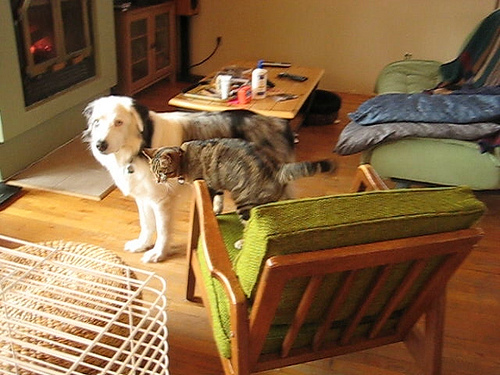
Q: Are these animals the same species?
A: No, they are dogs and cats.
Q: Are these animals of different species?
A: Yes, they are dogs and cats.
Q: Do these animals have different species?
A: Yes, they are dogs and cats.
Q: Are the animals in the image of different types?
A: Yes, they are dogs and cats.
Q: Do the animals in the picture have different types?
A: Yes, they are dogs and cats.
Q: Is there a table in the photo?
A: Yes, there is a table.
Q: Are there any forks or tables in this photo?
A: Yes, there is a table.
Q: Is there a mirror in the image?
A: No, there are no mirrors.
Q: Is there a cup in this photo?
A: Yes, there is a cup.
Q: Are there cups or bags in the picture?
A: Yes, there is a cup.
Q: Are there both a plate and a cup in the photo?
A: No, there is a cup but no plates.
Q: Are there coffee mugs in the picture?
A: No, there are no coffee mugs.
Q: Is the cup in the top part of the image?
A: Yes, the cup is in the top of the image.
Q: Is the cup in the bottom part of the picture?
A: No, the cup is in the top of the image.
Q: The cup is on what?
A: The cup is on the table.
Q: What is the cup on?
A: The cup is on the table.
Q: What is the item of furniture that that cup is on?
A: The piece of furniture is a table.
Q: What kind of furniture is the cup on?
A: The cup is on the table.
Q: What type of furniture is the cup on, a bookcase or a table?
A: The cup is on a table.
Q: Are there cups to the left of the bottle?
A: Yes, there is a cup to the left of the bottle.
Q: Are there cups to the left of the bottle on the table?
A: Yes, there is a cup to the left of the bottle.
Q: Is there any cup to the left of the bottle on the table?
A: Yes, there is a cup to the left of the bottle.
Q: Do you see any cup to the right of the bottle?
A: No, the cup is to the left of the bottle.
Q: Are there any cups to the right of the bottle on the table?
A: No, the cup is to the left of the bottle.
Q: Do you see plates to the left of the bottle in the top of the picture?
A: No, there is a cup to the left of the bottle.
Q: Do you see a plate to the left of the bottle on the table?
A: No, there is a cup to the left of the bottle.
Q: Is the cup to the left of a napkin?
A: No, the cup is to the left of the bottle.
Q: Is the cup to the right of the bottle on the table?
A: No, the cup is to the left of the bottle.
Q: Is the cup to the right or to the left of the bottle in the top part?
A: The cup is to the left of the bottle.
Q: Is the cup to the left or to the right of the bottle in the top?
A: The cup is to the left of the bottle.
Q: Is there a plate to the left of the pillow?
A: No, there is a cup to the left of the pillow.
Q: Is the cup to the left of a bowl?
A: No, the cup is to the left of the pillow.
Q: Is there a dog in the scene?
A: Yes, there is a dog.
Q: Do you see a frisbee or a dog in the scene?
A: Yes, there is a dog.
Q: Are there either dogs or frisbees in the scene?
A: Yes, there is a dog.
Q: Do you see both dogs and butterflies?
A: No, there is a dog but no butterflies.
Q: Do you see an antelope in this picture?
A: No, there are no antelopes.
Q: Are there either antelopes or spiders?
A: No, there are no antelopes or spiders.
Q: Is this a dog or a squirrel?
A: This is a dog.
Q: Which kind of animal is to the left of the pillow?
A: The animal is a dog.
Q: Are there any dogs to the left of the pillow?
A: Yes, there is a dog to the left of the pillow.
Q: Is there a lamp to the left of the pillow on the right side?
A: No, there is a dog to the left of the pillow.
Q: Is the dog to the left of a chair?
A: No, the dog is to the left of the pillow.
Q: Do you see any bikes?
A: No, there are no bikes.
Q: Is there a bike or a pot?
A: No, there are no bikes or pots.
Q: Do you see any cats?
A: Yes, there is a cat.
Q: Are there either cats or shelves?
A: Yes, there is a cat.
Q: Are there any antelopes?
A: No, there are no antelopes.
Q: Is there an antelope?
A: No, there are no antelopes.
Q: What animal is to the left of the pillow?
A: The animal is a cat.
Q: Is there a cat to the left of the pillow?
A: Yes, there is a cat to the left of the pillow.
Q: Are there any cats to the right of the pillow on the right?
A: No, the cat is to the left of the pillow.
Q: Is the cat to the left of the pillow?
A: Yes, the cat is to the left of the pillow.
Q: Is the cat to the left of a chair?
A: No, the cat is to the left of the pillow.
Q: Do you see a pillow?
A: Yes, there is a pillow.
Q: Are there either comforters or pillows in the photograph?
A: Yes, there is a pillow.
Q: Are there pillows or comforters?
A: Yes, there is a pillow.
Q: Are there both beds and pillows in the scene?
A: No, there is a pillow but no beds.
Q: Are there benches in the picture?
A: No, there are no benches.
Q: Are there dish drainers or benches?
A: No, there are no benches or dish drainers.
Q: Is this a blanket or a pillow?
A: This is a pillow.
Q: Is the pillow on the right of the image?
A: Yes, the pillow is on the right of the image.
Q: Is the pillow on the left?
A: No, the pillow is on the right of the image.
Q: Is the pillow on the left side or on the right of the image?
A: The pillow is on the right of the image.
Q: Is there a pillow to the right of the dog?
A: Yes, there is a pillow to the right of the dog.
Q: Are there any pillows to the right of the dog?
A: Yes, there is a pillow to the right of the dog.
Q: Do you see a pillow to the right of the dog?
A: Yes, there is a pillow to the right of the dog.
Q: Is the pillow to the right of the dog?
A: Yes, the pillow is to the right of the dog.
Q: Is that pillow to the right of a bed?
A: No, the pillow is to the right of the dog.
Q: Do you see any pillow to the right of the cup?
A: Yes, there is a pillow to the right of the cup.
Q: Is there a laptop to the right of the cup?
A: No, there is a pillow to the right of the cup.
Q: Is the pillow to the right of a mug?
A: No, the pillow is to the right of a cup.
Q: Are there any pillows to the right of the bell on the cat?
A: Yes, there is a pillow to the right of the bell.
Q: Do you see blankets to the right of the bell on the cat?
A: No, there is a pillow to the right of the bell.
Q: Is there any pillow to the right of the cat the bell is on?
A: Yes, there is a pillow to the right of the cat.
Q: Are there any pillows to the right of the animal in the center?
A: Yes, there is a pillow to the right of the cat.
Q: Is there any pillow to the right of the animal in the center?
A: Yes, there is a pillow to the right of the cat.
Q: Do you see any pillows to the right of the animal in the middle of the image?
A: Yes, there is a pillow to the right of the cat.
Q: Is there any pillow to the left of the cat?
A: No, the pillow is to the right of the cat.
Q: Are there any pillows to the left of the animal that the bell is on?
A: No, the pillow is to the right of the cat.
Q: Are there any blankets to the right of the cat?
A: No, there is a pillow to the right of the cat.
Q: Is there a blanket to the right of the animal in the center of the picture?
A: No, there is a pillow to the right of the cat.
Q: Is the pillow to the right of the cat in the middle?
A: Yes, the pillow is to the right of the cat.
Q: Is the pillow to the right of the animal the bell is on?
A: Yes, the pillow is to the right of the cat.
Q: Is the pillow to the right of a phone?
A: No, the pillow is to the right of the cat.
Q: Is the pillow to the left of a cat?
A: No, the pillow is to the right of a cat.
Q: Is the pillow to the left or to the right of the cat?
A: The pillow is to the right of the cat.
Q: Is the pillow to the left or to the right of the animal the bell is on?
A: The pillow is to the right of the cat.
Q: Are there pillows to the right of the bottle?
A: Yes, there is a pillow to the right of the bottle.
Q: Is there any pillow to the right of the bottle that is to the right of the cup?
A: Yes, there is a pillow to the right of the bottle.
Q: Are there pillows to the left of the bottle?
A: No, the pillow is to the right of the bottle.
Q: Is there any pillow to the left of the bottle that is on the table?
A: No, the pillow is to the right of the bottle.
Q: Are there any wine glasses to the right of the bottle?
A: No, there is a pillow to the right of the bottle.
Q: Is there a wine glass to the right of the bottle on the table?
A: No, there is a pillow to the right of the bottle.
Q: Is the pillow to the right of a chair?
A: No, the pillow is to the right of the bottle.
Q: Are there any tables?
A: Yes, there is a table.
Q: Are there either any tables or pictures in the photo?
A: Yes, there is a table.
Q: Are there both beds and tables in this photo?
A: No, there is a table but no beds.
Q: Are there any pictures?
A: No, there are no pictures.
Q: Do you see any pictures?
A: No, there are no pictures.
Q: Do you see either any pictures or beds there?
A: No, there are no pictures or beds.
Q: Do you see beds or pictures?
A: No, there are no pictures or beds.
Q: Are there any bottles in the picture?
A: Yes, there is a bottle.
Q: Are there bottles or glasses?
A: Yes, there is a bottle.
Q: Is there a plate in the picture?
A: No, there are no plates.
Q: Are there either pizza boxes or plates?
A: No, there are no plates or pizza boxes.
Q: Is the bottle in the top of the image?
A: Yes, the bottle is in the top of the image.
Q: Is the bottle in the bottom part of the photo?
A: No, the bottle is in the top of the image.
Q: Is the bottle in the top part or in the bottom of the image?
A: The bottle is in the top of the image.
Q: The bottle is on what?
A: The bottle is on the table.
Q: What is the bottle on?
A: The bottle is on the table.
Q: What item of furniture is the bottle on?
A: The bottle is on the table.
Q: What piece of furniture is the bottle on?
A: The bottle is on the table.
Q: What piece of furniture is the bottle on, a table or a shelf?
A: The bottle is on a table.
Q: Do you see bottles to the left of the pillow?
A: Yes, there is a bottle to the left of the pillow.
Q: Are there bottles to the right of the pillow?
A: No, the bottle is to the left of the pillow.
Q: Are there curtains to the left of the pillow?
A: No, there is a bottle to the left of the pillow.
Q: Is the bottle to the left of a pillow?
A: Yes, the bottle is to the left of a pillow.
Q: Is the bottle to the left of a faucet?
A: No, the bottle is to the left of a pillow.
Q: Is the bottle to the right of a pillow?
A: No, the bottle is to the left of a pillow.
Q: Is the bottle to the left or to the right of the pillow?
A: The bottle is to the left of the pillow.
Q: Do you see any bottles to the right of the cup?
A: Yes, there is a bottle to the right of the cup.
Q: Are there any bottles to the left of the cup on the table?
A: No, the bottle is to the right of the cup.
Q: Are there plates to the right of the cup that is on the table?
A: No, there is a bottle to the right of the cup.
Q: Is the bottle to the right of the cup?
A: Yes, the bottle is to the right of the cup.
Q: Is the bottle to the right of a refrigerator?
A: No, the bottle is to the right of the cup.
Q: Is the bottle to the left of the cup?
A: No, the bottle is to the right of the cup.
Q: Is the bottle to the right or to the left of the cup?
A: The bottle is to the right of the cup.